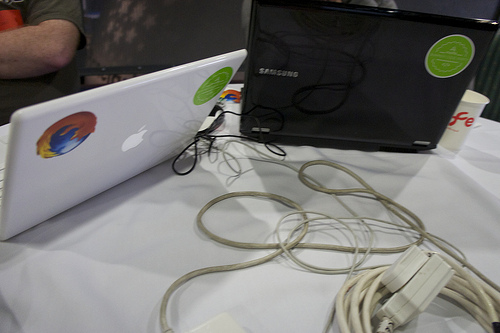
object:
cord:
[162, 160, 500, 328]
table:
[0, 82, 500, 333]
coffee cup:
[437, 90, 490, 151]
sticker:
[142, 116, 211, 176]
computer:
[242, 12, 500, 152]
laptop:
[14, 68, 197, 218]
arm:
[1, 1, 86, 81]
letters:
[456, 112, 476, 126]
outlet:
[375, 312, 395, 331]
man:
[6, 7, 104, 83]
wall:
[158, 0, 250, 62]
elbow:
[178, 145, 208, 168]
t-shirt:
[131, 104, 220, 148]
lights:
[86, 6, 159, 48]